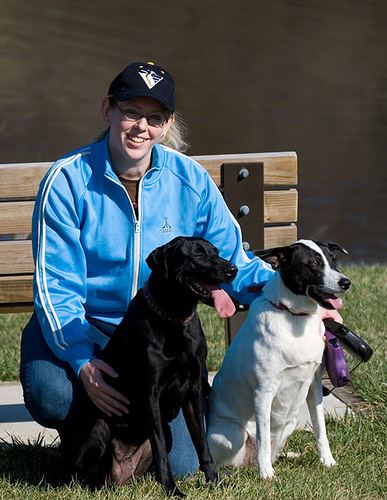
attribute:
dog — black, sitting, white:
[68, 237, 234, 489]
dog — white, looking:
[217, 232, 350, 474]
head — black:
[269, 239, 345, 312]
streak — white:
[301, 239, 334, 280]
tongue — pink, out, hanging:
[204, 282, 235, 322]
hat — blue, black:
[108, 65, 179, 110]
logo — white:
[137, 67, 166, 93]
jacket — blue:
[22, 143, 277, 367]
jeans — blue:
[30, 316, 207, 478]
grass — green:
[2, 267, 387, 498]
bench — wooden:
[5, 152, 306, 297]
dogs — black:
[77, 240, 345, 474]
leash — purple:
[323, 336, 348, 386]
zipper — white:
[119, 180, 143, 297]